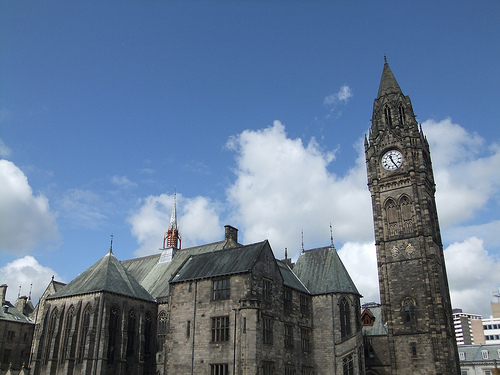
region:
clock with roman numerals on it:
[374, 137, 447, 192]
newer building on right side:
[466, 288, 498, 341]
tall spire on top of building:
[153, 188, 204, 243]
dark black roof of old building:
[185, 254, 259, 283]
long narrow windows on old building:
[55, 292, 93, 372]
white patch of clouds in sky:
[266, 191, 356, 245]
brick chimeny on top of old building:
[221, 214, 251, 242]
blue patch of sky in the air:
[106, 47, 133, 76]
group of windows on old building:
[198, 310, 241, 349]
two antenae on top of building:
[289, 222, 346, 245]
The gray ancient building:
[0, 53, 499, 373]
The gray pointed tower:
[362, 54, 465, 373]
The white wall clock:
[379, 145, 405, 172]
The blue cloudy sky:
[0, 0, 498, 318]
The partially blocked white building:
[449, 309, 498, 374]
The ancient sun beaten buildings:
[2, 54, 463, 374]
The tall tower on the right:
[363, 42, 461, 374]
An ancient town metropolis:
[0, 49, 498, 374]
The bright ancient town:
[2, 0, 499, 374]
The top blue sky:
[0, 0, 497, 87]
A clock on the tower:
[380, 149, 402, 169]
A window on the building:
[210, 315, 230, 342]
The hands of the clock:
[387, 153, 399, 168]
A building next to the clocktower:
[28, 189, 367, 374]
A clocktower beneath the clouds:
[364, 54, 464, 374]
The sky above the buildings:
[0, 2, 499, 316]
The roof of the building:
[56, 239, 361, 299]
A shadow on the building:
[366, 343, 383, 374]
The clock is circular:
[380, 148, 402, 170]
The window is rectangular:
[211, 316, 229, 343]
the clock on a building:
[363, 132, 428, 183]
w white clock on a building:
[371, 142, 411, 177]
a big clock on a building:
[371, 135, 425, 181]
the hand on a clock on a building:
[368, 139, 418, 181]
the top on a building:
[353, 28, 424, 132]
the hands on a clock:
[382, 150, 407, 175]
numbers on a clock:
[378, 143, 420, 179]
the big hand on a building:
[383, 144, 408, 182]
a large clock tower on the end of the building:
[357, 49, 467, 374]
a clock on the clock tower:
[376, 145, 405, 174]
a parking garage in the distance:
[451, 310, 487, 348]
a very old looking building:
[1, 46, 463, 373]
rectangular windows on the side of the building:
[209, 274, 232, 374]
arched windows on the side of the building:
[38, 301, 96, 368]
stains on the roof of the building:
[298, 247, 332, 284]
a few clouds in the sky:
[131, 106, 498, 314]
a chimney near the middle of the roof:
[220, 220, 243, 240]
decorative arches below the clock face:
[381, 190, 416, 235]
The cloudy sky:
[4, 27, 499, 317]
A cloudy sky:
[1, 25, 491, 327]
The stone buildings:
[21, 57, 475, 368]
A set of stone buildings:
[21, 55, 456, 370]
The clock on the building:
[371, 144, 419, 175]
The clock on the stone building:
[365, 148, 412, 174]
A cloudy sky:
[1, 26, 491, 311]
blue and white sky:
[163, 71, 378, 224]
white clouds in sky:
[242, 130, 327, 235]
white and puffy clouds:
[235, 137, 307, 210]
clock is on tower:
[379, 156, 407, 177]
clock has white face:
[370, 151, 403, 186]